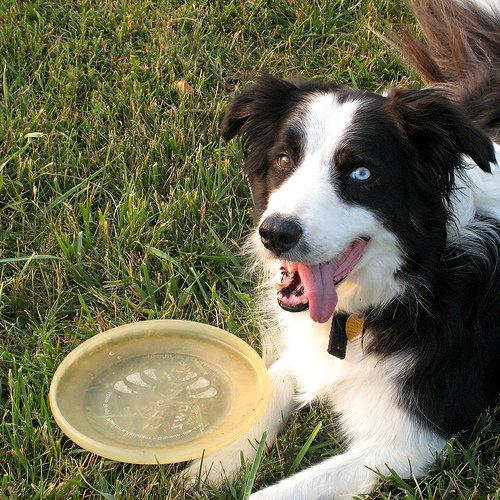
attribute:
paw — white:
[178, 431, 245, 490]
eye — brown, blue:
[271, 150, 297, 172]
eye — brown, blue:
[346, 162, 373, 185]